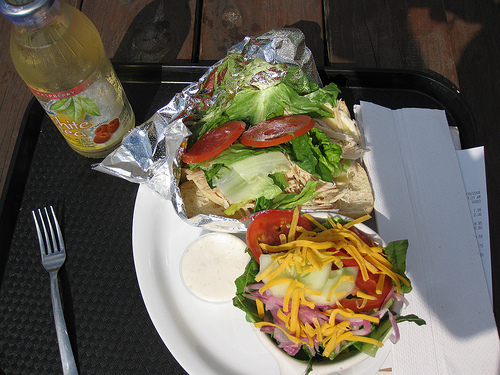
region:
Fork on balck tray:
[18, 192, 104, 374]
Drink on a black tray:
[2, 24, 135, 174]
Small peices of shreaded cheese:
[325, 323, 362, 345]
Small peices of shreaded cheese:
[275, 309, 319, 340]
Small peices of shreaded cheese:
[335, 281, 382, 322]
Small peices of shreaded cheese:
[294, 272, 350, 305]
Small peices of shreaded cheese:
[253, 267, 305, 303]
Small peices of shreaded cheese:
[259, 234, 310, 265]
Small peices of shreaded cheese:
[280, 219, 335, 263]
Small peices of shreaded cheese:
[317, 218, 401, 296]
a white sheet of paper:
[361, 100, 498, 373]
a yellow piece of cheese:
[257, 235, 315, 250]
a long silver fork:
[25, 202, 87, 374]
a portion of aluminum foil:
[92, 82, 204, 196]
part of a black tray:
[0, 58, 499, 373]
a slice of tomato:
[233, 110, 319, 148]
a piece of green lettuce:
[210, 143, 302, 176]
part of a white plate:
[130, 187, 362, 374]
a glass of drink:
[0, 0, 140, 159]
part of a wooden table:
[0, 0, 498, 176]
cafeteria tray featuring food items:
[1, 1, 474, 373]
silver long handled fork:
[16, 201, 91, 373]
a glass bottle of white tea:
[5, 0, 132, 155]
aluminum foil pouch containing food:
[115, 137, 175, 189]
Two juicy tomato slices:
[186, 118, 318, 160]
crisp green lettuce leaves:
[220, 158, 321, 197]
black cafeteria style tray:
[73, 198, 127, 373]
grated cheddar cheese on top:
[266, 230, 392, 358]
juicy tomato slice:
[246, 210, 327, 245]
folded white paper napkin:
[368, 104, 493, 371]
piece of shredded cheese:
[280, 278, 294, 315]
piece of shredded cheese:
[288, 288, 300, 337]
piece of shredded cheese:
[298, 288, 314, 310]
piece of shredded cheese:
[254, 318, 299, 346]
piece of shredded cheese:
[346, 333, 380, 349]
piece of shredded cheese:
[343, 213, 370, 230]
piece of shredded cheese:
[341, 243, 368, 280]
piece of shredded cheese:
[366, 254, 402, 296]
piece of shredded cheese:
[260, 254, 300, 281]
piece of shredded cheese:
[254, 300, 266, 320]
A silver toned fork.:
[30, 202, 82, 369]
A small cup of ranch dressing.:
[178, 230, 253, 302]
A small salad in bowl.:
[245, 223, 385, 353]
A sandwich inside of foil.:
[185, 99, 367, 216]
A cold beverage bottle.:
[9, 2, 143, 151]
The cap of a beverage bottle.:
[1, 0, 61, 29]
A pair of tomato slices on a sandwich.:
[179, 108, 319, 168]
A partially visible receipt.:
[452, 140, 496, 307]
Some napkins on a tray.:
[357, 98, 498, 371]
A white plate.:
[135, 96, 378, 371]